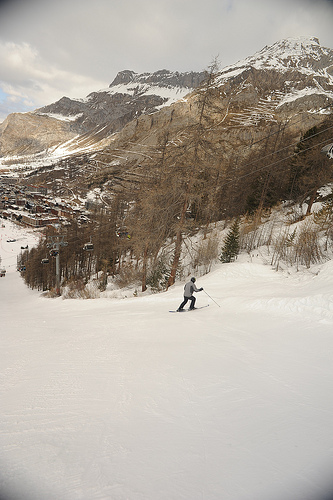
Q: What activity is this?
A: Skiing.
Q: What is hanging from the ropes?
A: Ski lifts.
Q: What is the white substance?
A: Snow.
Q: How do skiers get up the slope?
A: Ski lift.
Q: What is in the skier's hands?
A: Poles.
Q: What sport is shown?
A: Skiing.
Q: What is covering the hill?
A: Snow.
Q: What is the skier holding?
A: Poles.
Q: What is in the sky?
A: Clouds.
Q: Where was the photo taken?
A: Mountains.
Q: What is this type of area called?
A: Ski resort.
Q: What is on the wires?
A: Ski lifts.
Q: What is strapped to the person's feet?
A: Skis.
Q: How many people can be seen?
A: One.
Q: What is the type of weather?
A: Snow.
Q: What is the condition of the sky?
A: Cloudy.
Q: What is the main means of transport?
A: Cable cars.